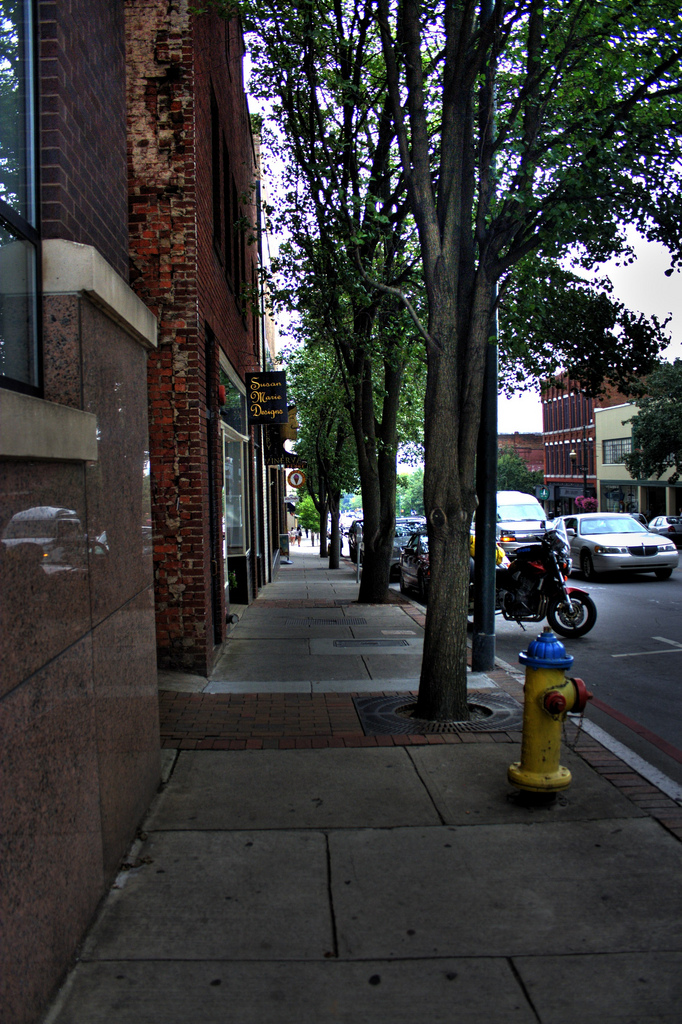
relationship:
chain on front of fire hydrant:
[565, 709, 582, 744] [507, 628, 590, 809]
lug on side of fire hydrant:
[544, 692, 565, 719] [507, 628, 590, 809]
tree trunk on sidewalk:
[420, 337, 468, 717] [55, 529, 663, 1021]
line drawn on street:
[588, 696, 677, 774] [491, 568, 679, 797]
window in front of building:
[2, 1, 41, 391] [0, 0, 160, 1023]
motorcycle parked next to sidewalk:
[488, 523, 596, 636] [55, 529, 663, 1021]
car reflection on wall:
[27, 535, 111, 595] [0, 462, 159, 1020]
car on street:
[553, 513, 677, 580] [491, 568, 679, 797]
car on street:
[647, 515, 678, 542] [491, 568, 679, 797]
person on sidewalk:
[295, 525, 302, 547] [55, 530, 662, 1021]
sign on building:
[241, 370, 286, 422] [153, 5, 284, 625]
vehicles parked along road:
[651, 514, 681, 542] [607, 581, 677, 764]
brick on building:
[175, 511, 195, 531] [125, 13, 251, 678]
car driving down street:
[553, 513, 677, 580] [491, 568, 679, 797]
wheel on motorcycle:
[547, 591, 596, 641] [488, 523, 596, 636]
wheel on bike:
[547, 591, 596, 642] [488, 533, 597, 634]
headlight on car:
[602, 545, 619, 553] [553, 513, 677, 580]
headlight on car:
[661, 547, 669, 550] [553, 513, 677, 580]